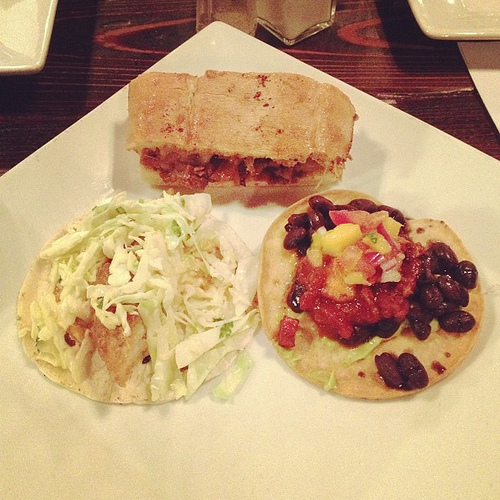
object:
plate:
[0, 20, 499, 500]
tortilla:
[19, 202, 224, 401]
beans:
[397, 352, 429, 386]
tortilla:
[257, 189, 484, 404]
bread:
[131, 70, 359, 189]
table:
[0, 0, 499, 177]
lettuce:
[175, 309, 259, 368]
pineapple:
[321, 218, 358, 256]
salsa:
[294, 244, 422, 338]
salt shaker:
[257, 0, 336, 43]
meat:
[208, 153, 240, 187]